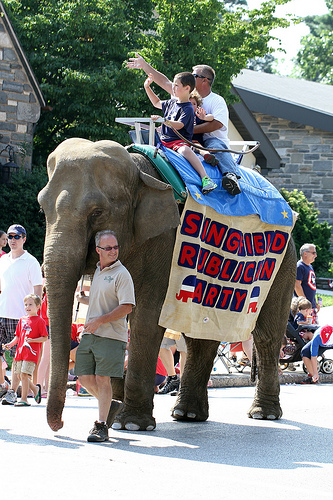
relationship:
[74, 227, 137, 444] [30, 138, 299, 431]
man leading an elephant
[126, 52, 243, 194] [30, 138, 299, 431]
three people on front of elephant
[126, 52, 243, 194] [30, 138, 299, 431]
three people in middle on elephant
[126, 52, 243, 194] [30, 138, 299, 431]
three people on elephant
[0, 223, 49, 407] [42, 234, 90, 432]
man and boy near elephant's trunk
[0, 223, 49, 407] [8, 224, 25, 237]
man and boy wearing a blue hat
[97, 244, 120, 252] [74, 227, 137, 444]
glasses worn by man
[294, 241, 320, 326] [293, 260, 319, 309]
man wearing blue shirt w/ star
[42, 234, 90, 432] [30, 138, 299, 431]
trunk of elephant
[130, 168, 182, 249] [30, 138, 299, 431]
left ear of elephant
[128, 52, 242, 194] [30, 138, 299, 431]
three people on an elephant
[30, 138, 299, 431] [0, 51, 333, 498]
elephant at an event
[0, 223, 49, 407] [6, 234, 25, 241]
man and boy wearing sunglasses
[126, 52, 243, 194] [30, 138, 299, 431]
three people on top of an elephant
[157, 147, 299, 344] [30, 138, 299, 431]
banner on an elephant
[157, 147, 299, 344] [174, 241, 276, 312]
banner for republican party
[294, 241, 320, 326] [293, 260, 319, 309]
man ia background in blue shirt w/ star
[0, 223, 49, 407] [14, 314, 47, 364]
man and boy in a red shirt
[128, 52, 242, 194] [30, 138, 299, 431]
three people on top of elephant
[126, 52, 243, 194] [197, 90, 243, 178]
three people wearing a white shirt & jeans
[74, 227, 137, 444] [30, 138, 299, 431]
man walking near elephant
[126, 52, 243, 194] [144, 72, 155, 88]
three people raising h hand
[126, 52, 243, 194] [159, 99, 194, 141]
three people wearing a blue shirt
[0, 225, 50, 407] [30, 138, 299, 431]
man and boy near elephant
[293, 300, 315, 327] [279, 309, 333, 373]
kid in a stroller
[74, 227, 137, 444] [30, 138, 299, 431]
man guiding elephant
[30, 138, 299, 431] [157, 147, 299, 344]
elephant has a banner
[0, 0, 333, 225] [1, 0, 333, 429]
stone buildings in background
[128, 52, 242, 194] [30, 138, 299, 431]
three people atop an elephant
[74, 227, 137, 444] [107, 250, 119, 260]
man guiding elephant is smiling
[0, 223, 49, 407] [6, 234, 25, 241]
man and boy has on sunglasses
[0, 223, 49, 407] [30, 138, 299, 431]
man and boy next to elephant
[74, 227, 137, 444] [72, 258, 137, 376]
man wearing a beige shirt & shorts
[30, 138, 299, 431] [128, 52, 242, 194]
elephant carrying three people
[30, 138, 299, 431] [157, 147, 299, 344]
elephant wearing a banner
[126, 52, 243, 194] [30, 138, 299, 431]
three people riding an elephant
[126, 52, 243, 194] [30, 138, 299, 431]
three people riding elephant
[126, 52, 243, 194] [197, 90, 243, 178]
three people wearing white shirt & jeans